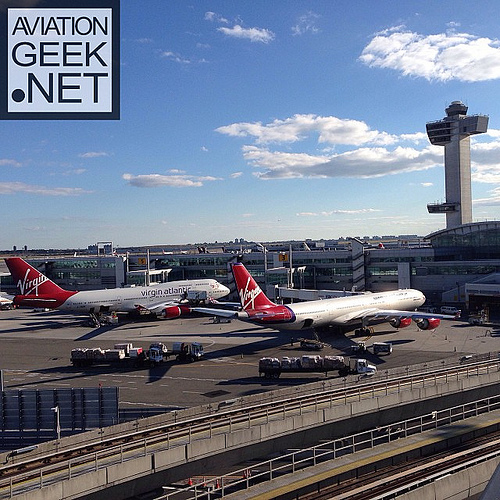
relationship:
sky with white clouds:
[8, 13, 487, 221] [224, 21, 488, 190]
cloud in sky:
[216, 105, 435, 186] [8, 13, 487, 221]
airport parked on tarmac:
[188, 261, 462, 351] [1, 326, 460, 366]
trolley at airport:
[286, 333, 329, 355] [5, 231, 499, 497]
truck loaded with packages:
[65, 340, 181, 370] [71, 342, 147, 363]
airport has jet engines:
[188, 261, 462, 351] [386, 316, 444, 333]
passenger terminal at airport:
[154, 245, 421, 285] [5, 231, 499, 497]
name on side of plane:
[140, 283, 191, 298] [3, 247, 234, 337]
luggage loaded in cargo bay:
[257, 352, 351, 371] [253, 348, 381, 377]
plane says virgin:
[3, 247, 234, 337] [10, 268, 53, 296]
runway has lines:
[9, 301, 320, 397] [107, 366, 236, 387]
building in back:
[154, 245, 421, 285] [8, 227, 500, 260]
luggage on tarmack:
[348, 335, 399, 358] [1, 326, 460, 366]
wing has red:
[156, 294, 246, 323] [165, 300, 198, 321]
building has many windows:
[154, 245, 421, 285] [250, 260, 397, 290]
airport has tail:
[188, 261, 462, 351] [185, 253, 299, 334]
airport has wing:
[188, 261, 462, 351] [366, 305, 460, 323]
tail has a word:
[185, 253, 299, 334] [236, 280, 265, 309]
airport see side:
[188, 261, 462, 351] [260, 294, 458, 337]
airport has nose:
[188, 261, 462, 351] [402, 280, 431, 310]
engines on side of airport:
[386, 316, 444, 333] [188, 261, 462, 351]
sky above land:
[8, 13, 487, 221] [2, 289, 476, 407]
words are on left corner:
[12, 12, 107, 110] [5, 4, 130, 138]